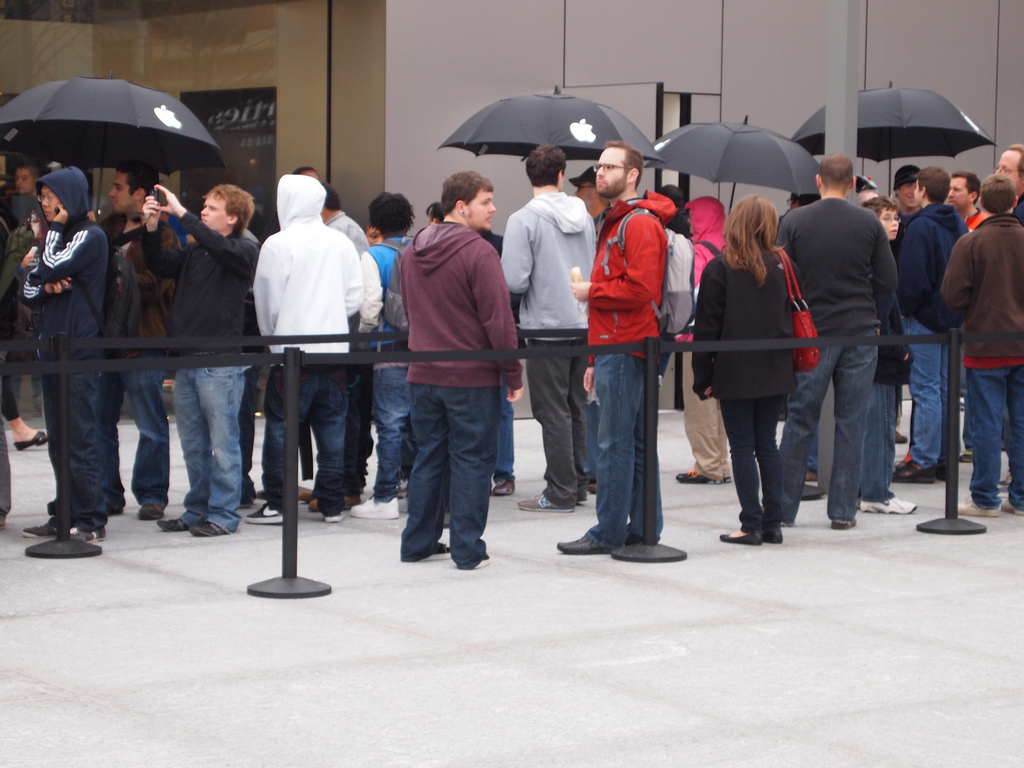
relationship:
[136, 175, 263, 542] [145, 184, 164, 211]
man holding camera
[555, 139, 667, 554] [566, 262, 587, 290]
man holding food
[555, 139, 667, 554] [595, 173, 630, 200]
man with beard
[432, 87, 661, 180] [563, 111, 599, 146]
umbrella with logo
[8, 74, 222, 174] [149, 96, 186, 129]
umbrella with logo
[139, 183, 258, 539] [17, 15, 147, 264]
man takes picture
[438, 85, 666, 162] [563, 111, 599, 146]
umbrella has logo